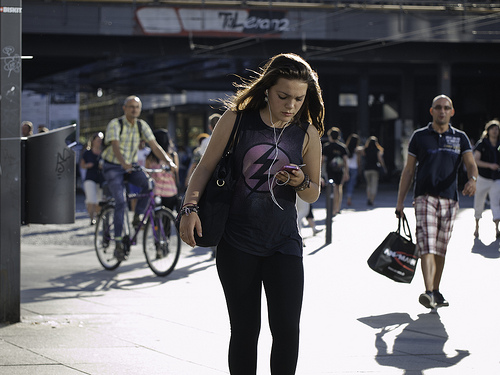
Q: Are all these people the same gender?
A: No, they are both male and female.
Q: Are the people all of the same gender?
A: No, they are both male and female.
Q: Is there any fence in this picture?
A: No, there are no fences.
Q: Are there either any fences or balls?
A: No, there are no fences or balls.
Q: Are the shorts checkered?
A: Yes, the shorts are checkered.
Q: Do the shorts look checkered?
A: Yes, the shorts are checkered.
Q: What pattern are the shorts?
A: The shorts are checkered.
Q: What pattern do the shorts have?
A: The shorts have checkered pattern.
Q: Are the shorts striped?
A: No, the shorts are checkered.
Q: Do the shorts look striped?
A: No, the shorts are checkered.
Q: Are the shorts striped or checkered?
A: The shorts are checkered.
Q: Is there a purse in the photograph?
A: Yes, there is a purse.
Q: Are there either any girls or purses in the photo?
A: Yes, there is a purse.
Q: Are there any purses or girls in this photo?
A: Yes, there is a purse.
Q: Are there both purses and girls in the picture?
A: Yes, there are both a purse and a girl.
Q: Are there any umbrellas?
A: No, there are no umbrellas.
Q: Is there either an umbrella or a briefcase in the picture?
A: No, there are no umbrellas or briefcases.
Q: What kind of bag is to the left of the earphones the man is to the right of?
A: The bag is a purse.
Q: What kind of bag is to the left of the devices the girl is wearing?
A: The bag is a purse.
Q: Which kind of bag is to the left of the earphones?
A: The bag is a purse.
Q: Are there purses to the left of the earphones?
A: Yes, there is a purse to the left of the earphones.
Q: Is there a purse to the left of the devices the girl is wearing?
A: Yes, there is a purse to the left of the earphones.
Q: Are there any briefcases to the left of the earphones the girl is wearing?
A: No, there is a purse to the left of the earphones.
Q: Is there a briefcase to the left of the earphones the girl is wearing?
A: No, there is a purse to the left of the earphones.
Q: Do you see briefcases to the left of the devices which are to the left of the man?
A: No, there is a purse to the left of the earphones.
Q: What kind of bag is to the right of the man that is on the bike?
A: The bag is a purse.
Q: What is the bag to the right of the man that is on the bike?
A: The bag is a purse.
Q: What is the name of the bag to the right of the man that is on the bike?
A: The bag is a purse.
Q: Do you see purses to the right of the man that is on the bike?
A: Yes, there is a purse to the right of the man.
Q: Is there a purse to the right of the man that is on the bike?
A: Yes, there is a purse to the right of the man.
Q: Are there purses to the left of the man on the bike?
A: No, the purse is to the right of the man.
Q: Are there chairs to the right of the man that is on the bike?
A: No, there is a purse to the right of the man.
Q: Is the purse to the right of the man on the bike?
A: Yes, the purse is to the right of the man.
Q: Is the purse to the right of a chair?
A: No, the purse is to the right of the man.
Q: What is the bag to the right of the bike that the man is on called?
A: The bag is a purse.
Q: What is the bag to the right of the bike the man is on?
A: The bag is a purse.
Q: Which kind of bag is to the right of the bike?
A: The bag is a purse.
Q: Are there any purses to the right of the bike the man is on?
A: Yes, there is a purse to the right of the bike.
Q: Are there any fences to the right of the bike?
A: No, there is a purse to the right of the bike.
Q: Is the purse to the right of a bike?
A: Yes, the purse is to the right of a bike.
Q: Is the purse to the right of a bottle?
A: No, the purse is to the right of a bike.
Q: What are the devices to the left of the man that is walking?
A: The devices are earphones.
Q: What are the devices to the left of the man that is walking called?
A: The devices are earphones.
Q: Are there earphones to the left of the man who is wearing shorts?
A: Yes, there are earphones to the left of the man.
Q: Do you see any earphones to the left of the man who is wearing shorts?
A: Yes, there are earphones to the left of the man.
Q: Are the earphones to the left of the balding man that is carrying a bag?
A: Yes, the earphones are to the left of the man.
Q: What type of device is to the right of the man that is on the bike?
A: The devices are earphones.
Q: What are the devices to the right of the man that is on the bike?
A: The devices are earphones.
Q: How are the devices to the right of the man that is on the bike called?
A: The devices are earphones.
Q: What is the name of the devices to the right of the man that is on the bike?
A: The devices are earphones.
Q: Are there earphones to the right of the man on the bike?
A: Yes, there are earphones to the right of the man.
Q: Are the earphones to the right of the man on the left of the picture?
A: Yes, the earphones are to the right of the man.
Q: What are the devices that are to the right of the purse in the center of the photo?
A: The devices are earphones.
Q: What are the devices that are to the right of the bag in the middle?
A: The devices are earphones.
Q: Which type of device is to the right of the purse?
A: The devices are earphones.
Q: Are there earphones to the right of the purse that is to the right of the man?
A: Yes, there are earphones to the right of the purse.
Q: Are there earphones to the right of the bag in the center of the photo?
A: Yes, there are earphones to the right of the purse.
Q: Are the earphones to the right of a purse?
A: Yes, the earphones are to the right of a purse.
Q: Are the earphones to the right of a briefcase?
A: No, the earphones are to the right of a purse.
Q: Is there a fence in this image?
A: No, there are no fences.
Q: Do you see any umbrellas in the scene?
A: No, there are no umbrellas.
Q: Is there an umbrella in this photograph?
A: No, there are no umbrellas.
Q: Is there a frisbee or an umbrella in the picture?
A: No, there are no umbrellas or frisbees.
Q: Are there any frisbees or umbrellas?
A: No, there are no umbrellas or frisbees.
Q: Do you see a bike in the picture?
A: Yes, there is a bike.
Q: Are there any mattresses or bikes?
A: Yes, there is a bike.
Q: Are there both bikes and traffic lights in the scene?
A: No, there is a bike but no traffic lights.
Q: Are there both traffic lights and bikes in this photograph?
A: No, there is a bike but no traffic lights.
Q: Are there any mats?
A: No, there are no mats.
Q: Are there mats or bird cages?
A: No, there are no mats or bird cages.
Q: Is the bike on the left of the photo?
A: Yes, the bike is on the left of the image.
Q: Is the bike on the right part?
A: No, the bike is on the left of the image.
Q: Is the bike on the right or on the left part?
A: The bike is on the left of the image.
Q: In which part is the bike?
A: The bike is on the left of the image.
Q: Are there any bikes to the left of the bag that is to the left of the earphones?
A: Yes, there is a bike to the left of the purse.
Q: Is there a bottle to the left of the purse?
A: No, there is a bike to the left of the purse.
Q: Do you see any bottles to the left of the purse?
A: No, there is a bike to the left of the purse.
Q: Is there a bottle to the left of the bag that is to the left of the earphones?
A: No, there is a bike to the left of the purse.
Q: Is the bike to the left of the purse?
A: Yes, the bike is to the left of the purse.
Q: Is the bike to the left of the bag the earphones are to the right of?
A: Yes, the bike is to the left of the purse.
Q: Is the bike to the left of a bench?
A: No, the bike is to the left of the purse.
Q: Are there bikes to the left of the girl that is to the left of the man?
A: Yes, there is a bike to the left of the girl.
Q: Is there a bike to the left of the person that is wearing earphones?
A: Yes, there is a bike to the left of the girl.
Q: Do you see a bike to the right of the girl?
A: No, the bike is to the left of the girl.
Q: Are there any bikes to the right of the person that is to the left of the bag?
A: No, the bike is to the left of the girl.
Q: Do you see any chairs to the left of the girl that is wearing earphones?
A: No, there is a bike to the left of the girl.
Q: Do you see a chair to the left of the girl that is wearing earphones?
A: No, there is a bike to the left of the girl.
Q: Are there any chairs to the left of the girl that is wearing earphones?
A: No, there is a bike to the left of the girl.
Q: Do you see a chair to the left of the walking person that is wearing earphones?
A: No, there is a bike to the left of the girl.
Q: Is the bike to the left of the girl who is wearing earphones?
A: Yes, the bike is to the left of the girl.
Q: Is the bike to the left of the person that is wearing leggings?
A: Yes, the bike is to the left of the girl.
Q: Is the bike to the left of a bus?
A: No, the bike is to the left of the girl.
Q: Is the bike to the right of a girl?
A: No, the bike is to the left of a girl.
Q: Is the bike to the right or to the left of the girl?
A: The bike is to the left of the girl.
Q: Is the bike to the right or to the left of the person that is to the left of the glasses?
A: The bike is to the left of the girl.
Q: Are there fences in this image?
A: No, there are no fences.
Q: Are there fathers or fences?
A: No, there are no fences or fathers.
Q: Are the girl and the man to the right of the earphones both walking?
A: Yes, both the girl and the man are walking.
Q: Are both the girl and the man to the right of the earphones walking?
A: Yes, both the girl and the man are walking.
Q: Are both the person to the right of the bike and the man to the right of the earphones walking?
A: Yes, both the girl and the man are walking.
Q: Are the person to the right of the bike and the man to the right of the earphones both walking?
A: Yes, both the girl and the man are walking.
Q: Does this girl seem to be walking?
A: Yes, the girl is walking.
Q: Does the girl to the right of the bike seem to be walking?
A: Yes, the girl is walking.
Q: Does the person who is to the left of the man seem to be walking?
A: Yes, the girl is walking.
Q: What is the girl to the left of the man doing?
A: The girl is walking.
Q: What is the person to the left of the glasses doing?
A: The girl is walking.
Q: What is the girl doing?
A: The girl is walking.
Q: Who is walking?
A: The girl is walking.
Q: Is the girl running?
A: No, the girl is walking.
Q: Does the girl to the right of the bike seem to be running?
A: No, the girl is walking.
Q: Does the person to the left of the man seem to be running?
A: No, the girl is walking.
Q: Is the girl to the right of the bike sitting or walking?
A: The girl is walking.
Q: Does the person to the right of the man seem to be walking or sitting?
A: The girl is walking.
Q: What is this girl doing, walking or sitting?
A: The girl is walking.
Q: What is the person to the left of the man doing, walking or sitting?
A: The girl is walking.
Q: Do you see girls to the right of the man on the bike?
A: Yes, there is a girl to the right of the man.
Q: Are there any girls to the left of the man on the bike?
A: No, the girl is to the right of the man.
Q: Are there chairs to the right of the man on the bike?
A: No, there is a girl to the right of the man.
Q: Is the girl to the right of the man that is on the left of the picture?
A: Yes, the girl is to the right of the man.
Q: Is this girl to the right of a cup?
A: No, the girl is to the right of the man.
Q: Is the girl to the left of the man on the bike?
A: No, the girl is to the right of the man.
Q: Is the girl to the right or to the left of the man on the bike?
A: The girl is to the right of the man.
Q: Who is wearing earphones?
A: The girl is wearing earphones.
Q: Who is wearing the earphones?
A: The girl is wearing earphones.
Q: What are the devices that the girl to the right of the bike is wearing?
A: The devices are earphones.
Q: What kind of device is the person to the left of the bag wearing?
A: The girl is wearing earphones.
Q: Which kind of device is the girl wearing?
A: The girl is wearing earphones.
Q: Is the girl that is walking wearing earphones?
A: Yes, the girl is wearing earphones.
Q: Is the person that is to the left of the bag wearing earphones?
A: Yes, the girl is wearing earphones.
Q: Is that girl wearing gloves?
A: No, the girl is wearing earphones.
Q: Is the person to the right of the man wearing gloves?
A: No, the girl is wearing earphones.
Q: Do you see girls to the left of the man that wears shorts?
A: Yes, there is a girl to the left of the man.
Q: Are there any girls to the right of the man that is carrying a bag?
A: No, the girl is to the left of the man.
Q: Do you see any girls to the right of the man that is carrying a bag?
A: No, the girl is to the left of the man.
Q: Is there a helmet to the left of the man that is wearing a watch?
A: No, there is a girl to the left of the man.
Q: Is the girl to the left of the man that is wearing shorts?
A: Yes, the girl is to the left of the man.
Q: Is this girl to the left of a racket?
A: No, the girl is to the left of the man.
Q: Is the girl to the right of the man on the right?
A: No, the girl is to the left of the man.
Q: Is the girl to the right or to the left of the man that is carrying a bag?
A: The girl is to the left of the man.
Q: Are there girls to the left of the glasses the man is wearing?
A: Yes, there is a girl to the left of the glasses.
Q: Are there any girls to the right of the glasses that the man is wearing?
A: No, the girl is to the left of the glasses.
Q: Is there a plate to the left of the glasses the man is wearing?
A: No, there is a girl to the left of the glasses.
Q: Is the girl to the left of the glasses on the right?
A: Yes, the girl is to the left of the glasses.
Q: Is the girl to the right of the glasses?
A: No, the girl is to the left of the glasses.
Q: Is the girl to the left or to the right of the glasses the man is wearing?
A: The girl is to the left of the glasses.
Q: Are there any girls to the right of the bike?
A: Yes, there is a girl to the right of the bike.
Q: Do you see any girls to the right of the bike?
A: Yes, there is a girl to the right of the bike.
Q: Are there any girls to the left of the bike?
A: No, the girl is to the right of the bike.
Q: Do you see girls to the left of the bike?
A: No, the girl is to the right of the bike.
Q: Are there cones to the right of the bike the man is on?
A: No, there is a girl to the right of the bike.